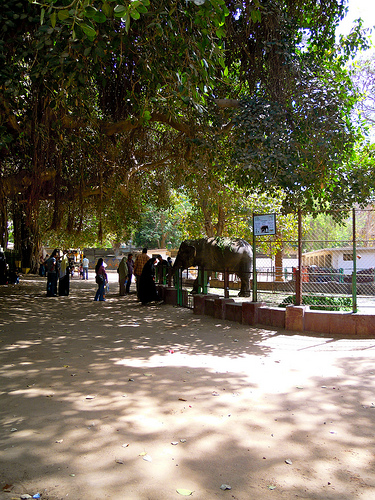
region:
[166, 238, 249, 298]
a large grey elephant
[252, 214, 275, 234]
a white visitor sign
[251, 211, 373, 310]
a tall chain link fence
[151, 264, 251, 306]
a short green metal fence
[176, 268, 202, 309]
a green metal gate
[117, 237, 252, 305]
people standing near elephant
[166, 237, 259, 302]
an elephant is standing behind the fence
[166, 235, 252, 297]
the trunk of the elephant is reaching outside the fence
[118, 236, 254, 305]
people are standing in front of an elephant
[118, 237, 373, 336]
the fence in between the elephant and people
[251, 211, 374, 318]
a sign board attached on top of the fence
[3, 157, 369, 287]
well grown trees with green leaves on them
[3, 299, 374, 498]
leaves are spread on the dirt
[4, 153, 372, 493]
the ground has shadows cast by the branches and leaves of the tree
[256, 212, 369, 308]
patch of green bush is visible on the ground behind the fence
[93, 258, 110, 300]
the woman is carrying a water bottle in her right hand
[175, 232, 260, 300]
an elephant at the park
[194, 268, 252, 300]
the fat legs of animal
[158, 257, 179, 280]
the long trunk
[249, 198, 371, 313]
a chain link fence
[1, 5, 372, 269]
trees over the park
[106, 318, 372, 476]
the casting on the ground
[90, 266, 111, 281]
a purple shirt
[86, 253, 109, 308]
a lady standing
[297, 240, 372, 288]
a white building in the back of elephant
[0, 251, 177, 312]
all the people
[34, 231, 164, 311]
people standing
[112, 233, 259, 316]
people standing close to the elephant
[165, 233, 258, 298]
an elephant in the gated area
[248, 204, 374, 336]
a tall fence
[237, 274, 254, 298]
back legs of the elephant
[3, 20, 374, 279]
trees providing shade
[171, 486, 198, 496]
a leaf on the ground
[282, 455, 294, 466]
a leaf on the ground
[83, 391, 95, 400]
a leaf on the ground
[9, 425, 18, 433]
a leaf on the ground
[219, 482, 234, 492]
leaf on the ground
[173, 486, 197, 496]
leaf on the ground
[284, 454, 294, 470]
leaf on the ground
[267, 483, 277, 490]
leaf on the ground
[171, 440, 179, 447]
leaf on the ground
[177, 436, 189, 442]
leaf on the ground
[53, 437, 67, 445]
leaf on the ground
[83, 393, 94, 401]
leaf on the ground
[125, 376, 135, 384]
leaf on the ground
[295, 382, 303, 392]
leaf on the ground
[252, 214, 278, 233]
A sign is on the fence.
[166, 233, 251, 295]
An elephant is in the fence.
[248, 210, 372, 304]
The fence is metal.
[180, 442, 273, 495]
Shadows are on the ground.